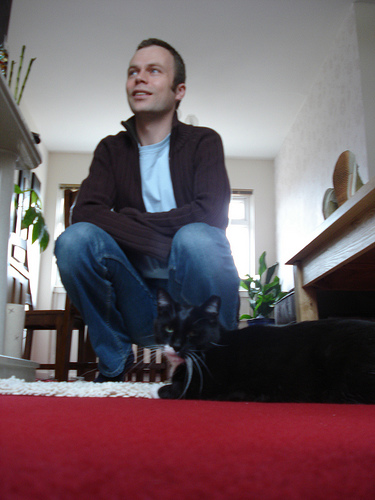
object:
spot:
[180, 353, 188, 356]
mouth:
[167, 353, 184, 363]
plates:
[331, 149, 364, 207]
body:
[224, 317, 374, 404]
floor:
[3, 388, 99, 441]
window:
[226, 196, 251, 280]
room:
[0, 0, 375, 500]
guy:
[53, 37, 241, 381]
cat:
[152, 286, 375, 405]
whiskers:
[178, 349, 213, 399]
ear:
[199, 294, 221, 319]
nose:
[172, 341, 181, 352]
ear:
[156, 285, 179, 314]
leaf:
[258, 251, 267, 278]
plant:
[238, 251, 289, 320]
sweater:
[70, 114, 231, 274]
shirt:
[137, 133, 177, 215]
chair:
[23, 188, 95, 387]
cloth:
[0, 372, 54, 393]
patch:
[160, 342, 172, 350]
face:
[126, 45, 175, 115]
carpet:
[0, 393, 374, 500]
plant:
[13, 184, 49, 254]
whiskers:
[116, 343, 167, 374]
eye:
[164, 323, 174, 332]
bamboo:
[14, 44, 25, 99]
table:
[284, 178, 373, 322]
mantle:
[0, 71, 43, 172]